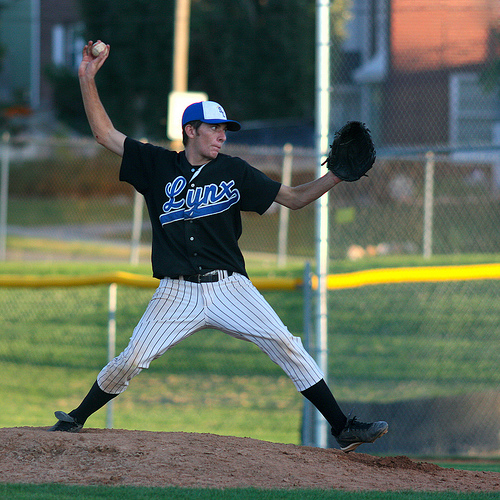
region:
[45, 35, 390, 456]
A baseball pitcher in action.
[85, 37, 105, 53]
A baseball in the hands of a player.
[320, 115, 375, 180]
A baseball glove in the hands of a player.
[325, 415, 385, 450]
A black sneaker worn by a baseball player.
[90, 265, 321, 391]
A white pair of baseball pants.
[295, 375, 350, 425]
A black sock worn by a baseball pitcher.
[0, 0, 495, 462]
The large fence separating the field from everything else.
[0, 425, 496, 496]
The baseball field in which the game is played.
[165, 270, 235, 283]
The belt of a baseball pitcher.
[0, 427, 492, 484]
A pile of dirt in which the baseball player is standing.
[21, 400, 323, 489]
pitching mound is dirt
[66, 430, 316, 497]
pitching mound is dirt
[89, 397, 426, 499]
pitching mound is dirt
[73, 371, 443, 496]
pitching mound is dirt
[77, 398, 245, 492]
pitching mound is dirt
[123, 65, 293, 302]
a man wearing a hat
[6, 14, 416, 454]
a baseball player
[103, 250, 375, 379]
black and white striped pants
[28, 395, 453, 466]
black athletic shoes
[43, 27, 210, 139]
a baseball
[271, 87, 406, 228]
a black baseball glove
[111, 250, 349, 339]
a black belt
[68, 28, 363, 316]
a man wearing a black and blue shirt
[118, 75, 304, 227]
a man wearing a blue and white hat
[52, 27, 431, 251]
a man holding a baseball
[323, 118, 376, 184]
A black catcher's mitt.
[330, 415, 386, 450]
A black and white cleat.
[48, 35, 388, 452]
A man throwing a ball.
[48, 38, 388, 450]
A baseball player.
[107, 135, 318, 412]
A baseball uniform.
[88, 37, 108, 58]
A red and white baseball.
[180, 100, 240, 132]
A blue and white hat.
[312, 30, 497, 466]
A tall metal fence.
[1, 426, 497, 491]
Brown dirt in a baseball field.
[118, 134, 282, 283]
A black uniform shirt.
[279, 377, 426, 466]
shoes are dark black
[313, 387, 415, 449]
shoes are dark black